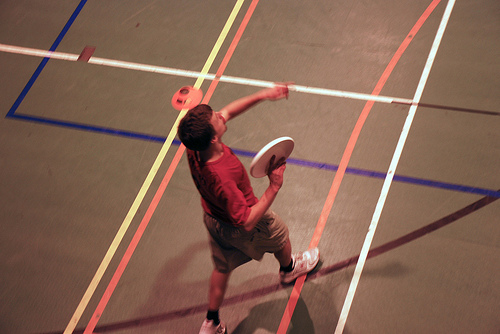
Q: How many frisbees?
A: 1.